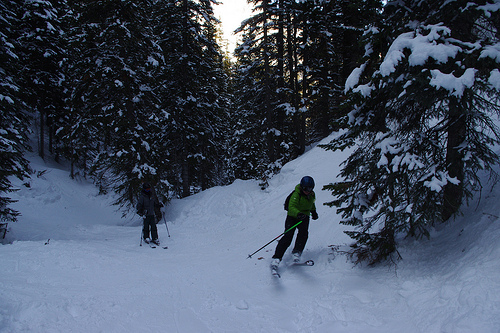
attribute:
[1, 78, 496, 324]
mountain — here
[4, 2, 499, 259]
forest — here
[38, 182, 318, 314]
snow — white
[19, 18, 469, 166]
trees — evergreen, here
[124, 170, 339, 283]
skiers — here, skiing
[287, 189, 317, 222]
jacket — green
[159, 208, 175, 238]
ski pole — yellow, blue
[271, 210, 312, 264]
pants — black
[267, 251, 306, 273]
shoes — white, blue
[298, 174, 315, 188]
helmet — blue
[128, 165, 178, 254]
person — here, skiing